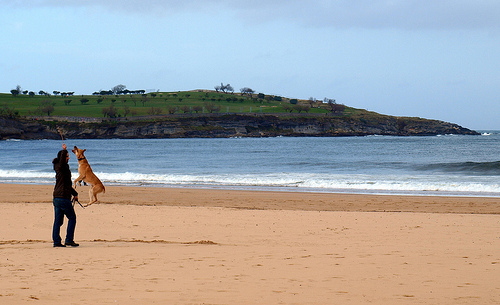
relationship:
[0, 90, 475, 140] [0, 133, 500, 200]
cliff leading to water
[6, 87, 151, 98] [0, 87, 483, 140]
animals walking on land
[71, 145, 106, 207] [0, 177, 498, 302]
animals walking on land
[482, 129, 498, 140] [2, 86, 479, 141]
water splashing on cliff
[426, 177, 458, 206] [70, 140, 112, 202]
ground playing with dog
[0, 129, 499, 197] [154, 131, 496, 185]
water in ocean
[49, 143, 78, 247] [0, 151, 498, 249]
man standing on beach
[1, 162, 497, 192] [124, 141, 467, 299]
wave breaking on beach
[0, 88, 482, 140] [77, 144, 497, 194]
cliff by ocean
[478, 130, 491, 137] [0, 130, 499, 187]
boat in ocean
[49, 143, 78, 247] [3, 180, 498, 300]
man standing on beach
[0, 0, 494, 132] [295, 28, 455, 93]
cloud are in sky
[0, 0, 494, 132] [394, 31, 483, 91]
cloud are in sky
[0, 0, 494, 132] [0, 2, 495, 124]
cloud are in sky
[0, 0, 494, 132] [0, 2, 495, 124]
cloud in sky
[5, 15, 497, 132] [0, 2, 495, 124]
cloud in sky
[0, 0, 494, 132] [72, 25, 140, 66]
cloud are in sky